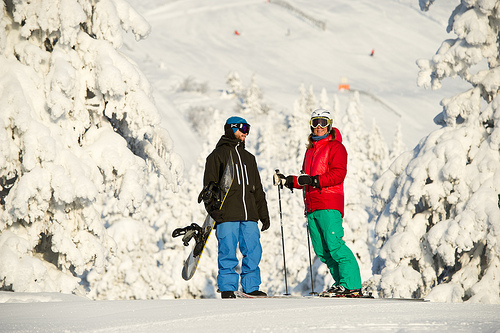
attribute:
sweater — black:
[205, 138, 261, 218]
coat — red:
[290, 133, 344, 213]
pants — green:
[298, 195, 367, 294]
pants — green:
[290, 203, 380, 302]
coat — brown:
[192, 145, 272, 239]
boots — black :
[218, 289, 269, 302]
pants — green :
[302, 207, 362, 287]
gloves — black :
[259, 210, 270, 237]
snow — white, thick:
[78, 299, 205, 332]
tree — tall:
[375, 3, 498, 306]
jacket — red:
[294, 126, 350, 216]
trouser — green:
[303, 210, 362, 290]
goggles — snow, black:
[235, 122, 249, 135]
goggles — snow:
[309, 118, 334, 128]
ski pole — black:
[271, 168, 291, 295]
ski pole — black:
[298, 167, 318, 297]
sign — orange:
[336, 81, 352, 95]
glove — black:
[297, 174, 319, 189]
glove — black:
[260, 215, 271, 231]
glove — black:
[209, 207, 227, 223]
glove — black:
[272, 174, 288, 186]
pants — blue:
[214, 220, 264, 295]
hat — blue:
[226, 118, 247, 135]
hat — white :
[309, 111, 333, 122]